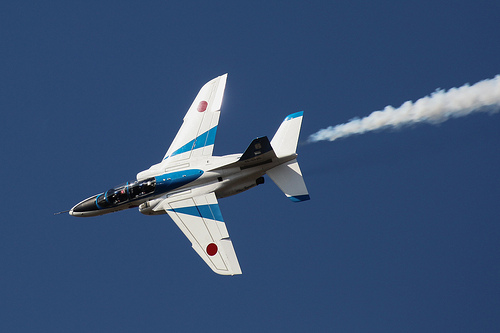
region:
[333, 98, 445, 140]
Smoking coming out of back of plane.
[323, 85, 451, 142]
Smoke is white coming out of back of plane.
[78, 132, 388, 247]
Plane is mostly white in color.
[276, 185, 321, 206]
Tip of tail is blue.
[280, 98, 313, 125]
Tip of tail is blue.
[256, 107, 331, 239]
Tail is mostly white.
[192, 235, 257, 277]
Red circle on wing of plane.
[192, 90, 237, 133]
Red circle on wing of plane.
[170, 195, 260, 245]
Blue marking on wing.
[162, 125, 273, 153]
Blue marking on wing.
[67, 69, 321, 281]
a jet in the air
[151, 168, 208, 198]
the jet has blue on it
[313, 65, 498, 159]
the jet is leaving a vapor trail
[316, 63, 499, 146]
the vapor trail is white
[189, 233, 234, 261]
the jet has red dots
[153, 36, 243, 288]
the jet has two wings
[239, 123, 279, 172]
the jet has a tail fin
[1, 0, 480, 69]
the sky is clear and blue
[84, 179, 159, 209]
the cockpit door is clear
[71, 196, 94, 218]
the nose of the jet is black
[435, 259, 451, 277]
part of the sky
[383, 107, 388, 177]
part of a smoke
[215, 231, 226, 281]
wing of a plane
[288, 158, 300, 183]
back of a plane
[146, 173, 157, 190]
top of a plane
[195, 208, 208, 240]
side of a plane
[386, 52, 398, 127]
part of jet smoke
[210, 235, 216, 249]
red part on a plane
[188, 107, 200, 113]
side of a plane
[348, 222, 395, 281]
part of the sky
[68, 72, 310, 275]
the plane is in the air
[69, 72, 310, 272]
the plane is white and blue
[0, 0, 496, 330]
the sky is dark blue and clear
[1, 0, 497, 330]
the plane is flying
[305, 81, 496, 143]
the plane has smoke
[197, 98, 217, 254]
the plane has red dots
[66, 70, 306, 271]
the plane is headed downward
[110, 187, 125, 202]
the plane has a driver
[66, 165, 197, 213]
the plane is pointy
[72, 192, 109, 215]
the plane has a black nose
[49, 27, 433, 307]
an airplane in the sky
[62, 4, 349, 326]
an airplane flying sideways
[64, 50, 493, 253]
an airplane making a trail of smoke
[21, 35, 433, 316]
a white and blue airplane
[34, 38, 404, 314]
a jet in the sky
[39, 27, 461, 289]
a jet flying in the sky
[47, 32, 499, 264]
a jet with a cloud of smoke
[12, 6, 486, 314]
a jet with a trail of smoke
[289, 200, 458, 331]
a blue clear sky